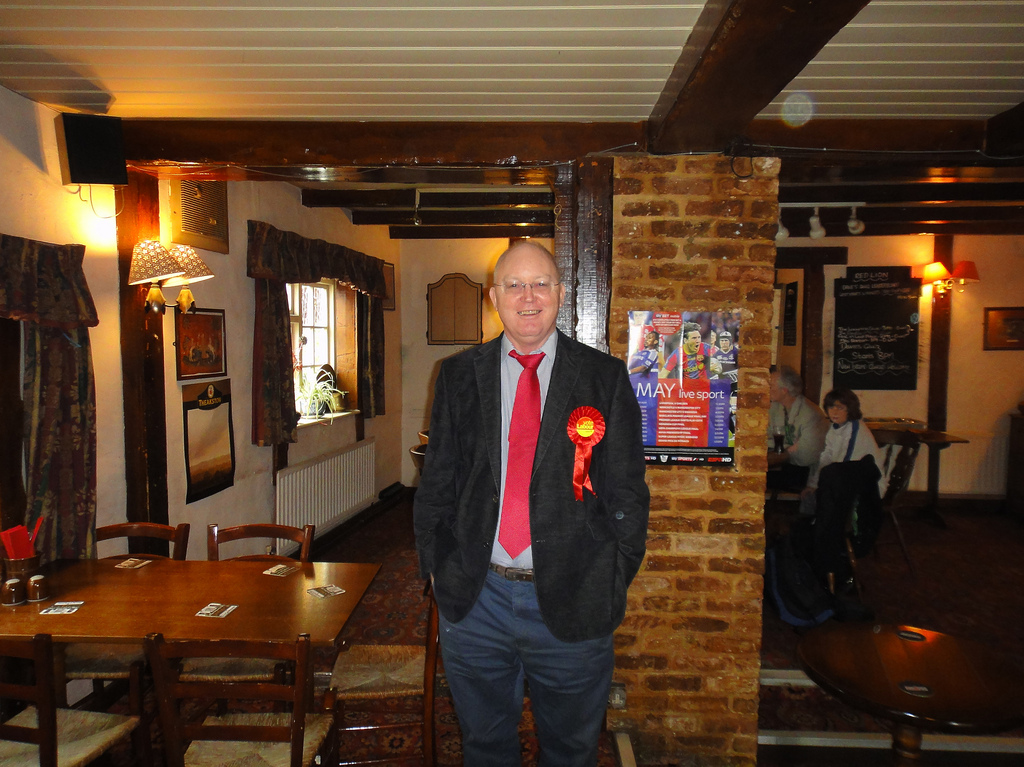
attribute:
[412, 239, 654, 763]
man — standing, smiling, facing camera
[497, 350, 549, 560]
tie — long, red, plain, pink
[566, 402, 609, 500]
ribbon — red, yellow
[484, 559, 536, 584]
belt — black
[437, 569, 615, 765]
pants — blue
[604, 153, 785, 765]
wall — brick, small, column, support beam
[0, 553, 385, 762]
table — wooden, wood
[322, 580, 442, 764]
chair — wood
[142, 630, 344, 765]
chair — wood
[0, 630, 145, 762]
chair — wood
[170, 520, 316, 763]
chair — wood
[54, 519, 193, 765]
chair — wood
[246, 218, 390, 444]
drapes — hanging, dark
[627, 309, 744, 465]
poster — red, purple, hanging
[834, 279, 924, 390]
board — black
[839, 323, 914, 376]
writing — white, chalk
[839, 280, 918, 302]
writing — white, chalk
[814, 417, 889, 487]
shirt — white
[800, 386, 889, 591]
woman — sitting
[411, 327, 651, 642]
jacket — black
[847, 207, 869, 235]
light fixture — white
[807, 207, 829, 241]
light fixture — white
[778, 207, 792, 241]
light fixture — white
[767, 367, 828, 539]
man — sitting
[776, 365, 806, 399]
hair — gray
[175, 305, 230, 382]
painting — framed, hanging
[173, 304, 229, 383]
frame — black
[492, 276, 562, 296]
glasses — eye glasses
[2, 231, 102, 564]
curtains — hanging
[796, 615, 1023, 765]
table — wood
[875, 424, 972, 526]
table — wood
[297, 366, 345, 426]
plant — green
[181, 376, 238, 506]
picture — hanging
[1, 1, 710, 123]
ceiling panels — wood, slat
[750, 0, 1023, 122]
ceiling panels — wood, slat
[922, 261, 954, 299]
light fixture — on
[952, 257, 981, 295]
light fixture — out